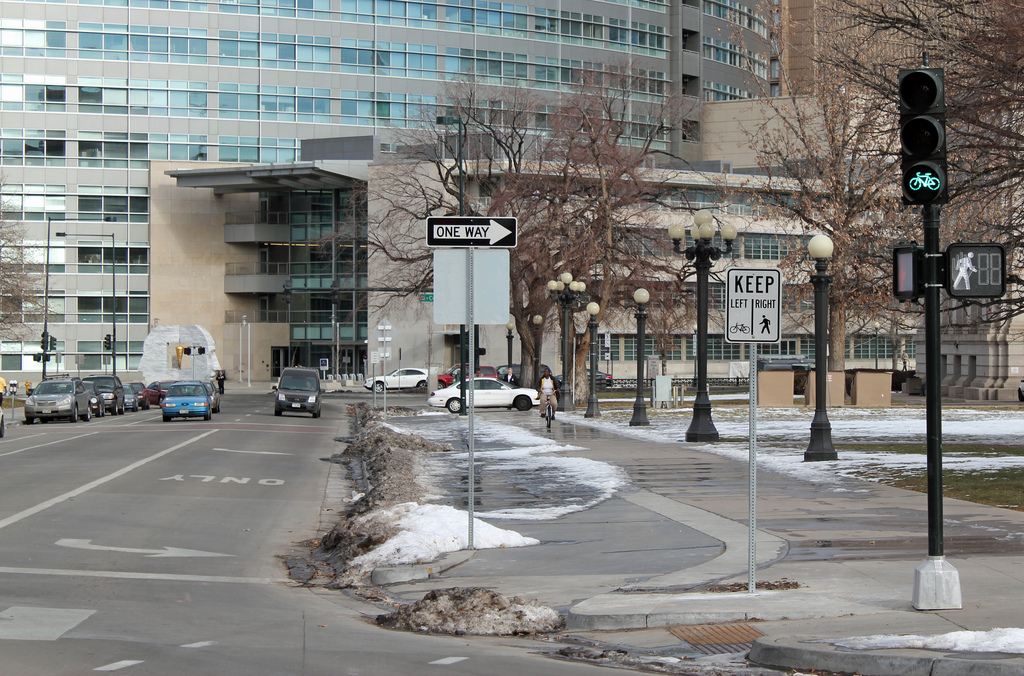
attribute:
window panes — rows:
[2, 3, 683, 140]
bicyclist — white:
[454, 358, 571, 428]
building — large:
[39, 105, 450, 503]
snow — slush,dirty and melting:
[348, 529, 552, 676]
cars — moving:
[104, 351, 329, 431]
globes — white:
[495, 233, 761, 352]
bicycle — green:
[812, 116, 972, 337]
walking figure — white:
[862, 231, 999, 357]